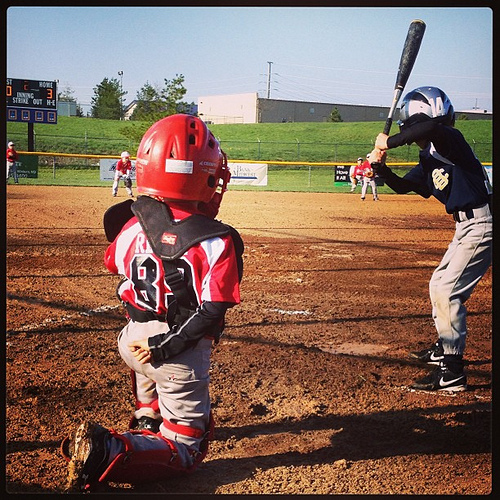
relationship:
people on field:
[61, 113, 241, 495] [5, 101, 497, 498]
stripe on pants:
[160, 414, 208, 441] [61, 295, 276, 457]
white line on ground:
[256, 301, 313, 322] [6, 176, 491, 494]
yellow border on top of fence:
[16, 148, 492, 170] [6, 146, 496, 186]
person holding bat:
[364, 85, 496, 392] [367, 21, 429, 161]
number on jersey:
[124, 255, 161, 317] [103, 209, 240, 314]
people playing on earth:
[6, 87, 498, 495] [5, 174, 492, 496]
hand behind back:
[125, 333, 157, 365] [92, 196, 251, 368]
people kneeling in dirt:
[61, 113, 241, 495] [8, 182, 495, 497]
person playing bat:
[368, 85, 495, 392] [370, 19, 426, 170]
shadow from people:
[221, 392, 491, 479] [61, 113, 241, 495]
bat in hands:
[351, 18, 431, 162] [347, 131, 387, 182]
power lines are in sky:
[178, 44, 470, 106] [8, 7, 493, 102]